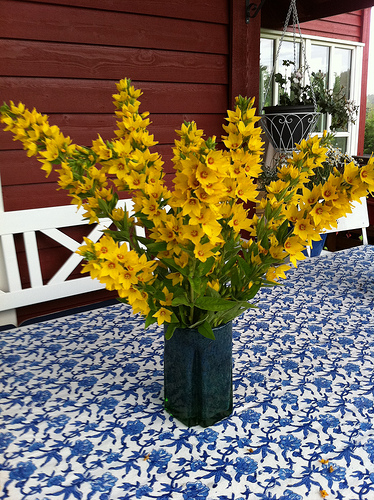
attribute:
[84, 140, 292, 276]
flower — yellow, vase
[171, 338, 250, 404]
vase — black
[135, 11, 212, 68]
wall — wood, red, brown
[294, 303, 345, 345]
table — blue